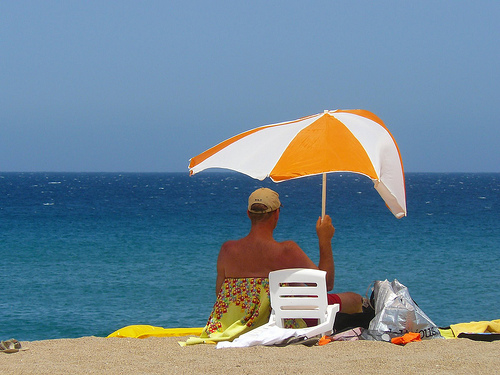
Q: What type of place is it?
A: It is an ocean.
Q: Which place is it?
A: It is an ocean.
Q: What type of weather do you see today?
A: It is clear.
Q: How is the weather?
A: It is clear.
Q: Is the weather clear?
A: Yes, it is clear.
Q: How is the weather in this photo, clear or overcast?
A: It is clear.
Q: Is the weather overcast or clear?
A: It is clear.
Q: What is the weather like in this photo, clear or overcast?
A: It is clear.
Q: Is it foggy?
A: No, it is clear.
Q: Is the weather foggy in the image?
A: No, it is clear.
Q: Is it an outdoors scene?
A: Yes, it is outdoors.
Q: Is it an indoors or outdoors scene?
A: It is outdoors.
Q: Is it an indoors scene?
A: No, it is outdoors.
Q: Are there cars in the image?
A: No, there are no cars.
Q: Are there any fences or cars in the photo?
A: No, there are no cars or fences.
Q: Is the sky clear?
A: Yes, the sky is clear.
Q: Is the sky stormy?
A: No, the sky is clear.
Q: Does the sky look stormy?
A: No, the sky is clear.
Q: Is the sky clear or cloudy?
A: The sky is clear.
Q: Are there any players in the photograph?
A: No, there are no players.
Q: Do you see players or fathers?
A: No, there are no players or fathers.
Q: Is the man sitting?
A: Yes, the man is sitting.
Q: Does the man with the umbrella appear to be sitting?
A: Yes, the man is sitting.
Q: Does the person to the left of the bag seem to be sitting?
A: Yes, the man is sitting.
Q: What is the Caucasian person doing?
A: The man is sitting.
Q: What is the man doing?
A: The man is sitting.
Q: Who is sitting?
A: The man is sitting.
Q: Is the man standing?
A: No, the man is sitting.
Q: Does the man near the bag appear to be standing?
A: No, the man is sitting.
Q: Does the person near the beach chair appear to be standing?
A: No, the man is sitting.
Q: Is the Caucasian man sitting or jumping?
A: The man is sitting.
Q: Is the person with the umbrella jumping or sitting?
A: The man is sitting.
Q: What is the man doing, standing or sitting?
A: The man is sitting.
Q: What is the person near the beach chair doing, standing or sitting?
A: The man is sitting.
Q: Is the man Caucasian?
A: Yes, the man is caucasian.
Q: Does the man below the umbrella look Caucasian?
A: Yes, the man is caucasian.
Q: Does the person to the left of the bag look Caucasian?
A: Yes, the man is caucasian.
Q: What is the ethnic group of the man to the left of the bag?
A: The man is caucasian.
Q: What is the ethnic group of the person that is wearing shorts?
A: The man is caucasian.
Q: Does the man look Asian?
A: No, the man is caucasian.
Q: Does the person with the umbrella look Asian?
A: No, the man is caucasian.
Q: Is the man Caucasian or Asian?
A: The man is caucasian.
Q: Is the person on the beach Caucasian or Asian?
A: The man is caucasian.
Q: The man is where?
A: The man is on the beach.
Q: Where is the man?
A: The man is on the beach.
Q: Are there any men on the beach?
A: Yes, there is a man on the beach.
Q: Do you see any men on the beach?
A: Yes, there is a man on the beach.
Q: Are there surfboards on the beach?
A: No, there is a man on the beach.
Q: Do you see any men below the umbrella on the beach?
A: Yes, there is a man below the umbrella.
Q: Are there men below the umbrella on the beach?
A: Yes, there is a man below the umbrella.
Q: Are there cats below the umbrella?
A: No, there is a man below the umbrella.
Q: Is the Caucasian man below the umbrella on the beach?
A: Yes, the man is below the umbrella.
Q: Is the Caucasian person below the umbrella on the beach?
A: Yes, the man is below the umbrella.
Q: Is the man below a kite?
A: No, the man is below the umbrella.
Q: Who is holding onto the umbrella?
A: The man is holding onto the umbrella.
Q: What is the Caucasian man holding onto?
A: The man is holding onto the umbrella.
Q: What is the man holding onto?
A: The man is holding onto the umbrella.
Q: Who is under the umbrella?
A: The man is under the umbrella.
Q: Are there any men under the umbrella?
A: Yes, there is a man under the umbrella.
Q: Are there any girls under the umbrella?
A: No, there is a man under the umbrella.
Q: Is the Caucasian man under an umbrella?
A: Yes, the man is under an umbrella.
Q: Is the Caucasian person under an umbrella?
A: Yes, the man is under an umbrella.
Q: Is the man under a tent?
A: No, the man is under an umbrella.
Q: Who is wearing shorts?
A: The man is wearing shorts.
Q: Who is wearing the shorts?
A: The man is wearing shorts.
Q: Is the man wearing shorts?
A: Yes, the man is wearing shorts.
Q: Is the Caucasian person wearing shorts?
A: Yes, the man is wearing shorts.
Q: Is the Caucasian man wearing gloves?
A: No, the man is wearing shorts.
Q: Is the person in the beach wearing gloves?
A: No, the man is wearing shorts.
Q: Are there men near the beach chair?
A: Yes, there is a man near the beach chair.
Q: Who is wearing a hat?
A: The man is wearing a hat.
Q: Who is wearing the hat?
A: The man is wearing a hat.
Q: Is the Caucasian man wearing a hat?
A: Yes, the man is wearing a hat.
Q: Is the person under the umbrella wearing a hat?
A: Yes, the man is wearing a hat.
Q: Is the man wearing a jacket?
A: No, the man is wearing a hat.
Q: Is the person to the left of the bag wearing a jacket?
A: No, the man is wearing a hat.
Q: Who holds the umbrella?
A: The man holds the umbrella.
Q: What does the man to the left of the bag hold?
A: The man holds the umbrella.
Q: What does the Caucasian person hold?
A: The man holds the umbrella.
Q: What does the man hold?
A: The man holds the umbrella.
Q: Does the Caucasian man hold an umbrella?
A: Yes, the man holds an umbrella.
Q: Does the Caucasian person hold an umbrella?
A: Yes, the man holds an umbrella.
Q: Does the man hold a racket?
A: No, the man holds an umbrella.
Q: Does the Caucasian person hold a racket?
A: No, the man holds an umbrella.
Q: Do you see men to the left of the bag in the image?
A: Yes, there is a man to the left of the bag.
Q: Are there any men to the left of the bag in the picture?
A: Yes, there is a man to the left of the bag.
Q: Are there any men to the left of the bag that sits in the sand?
A: Yes, there is a man to the left of the bag.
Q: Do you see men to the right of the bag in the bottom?
A: No, the man is to the left of the bag.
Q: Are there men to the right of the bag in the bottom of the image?
A: No, the man is to the left of the bag.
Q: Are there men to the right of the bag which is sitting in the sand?
A: No, the man is to the left of the bag.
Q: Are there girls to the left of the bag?
A: No, there is a man to the left of the bag.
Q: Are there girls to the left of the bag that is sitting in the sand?
A: No, there is a man to the left of the bag.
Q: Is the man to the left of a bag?
A: Yes, the man is to the left of a bag.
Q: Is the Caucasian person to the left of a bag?
A: Yes, the man is to the left of a bag.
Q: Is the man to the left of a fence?
A: No, the man is to the left of a bag.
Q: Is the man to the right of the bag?
A: No, the man is to the left of the bag.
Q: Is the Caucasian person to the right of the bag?
A: No, the man is to the left of the bag.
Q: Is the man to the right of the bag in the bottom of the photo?
A: No, the man is to the left of the bag.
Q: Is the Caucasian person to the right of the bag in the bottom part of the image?
A: No, the man is to the left of the bag.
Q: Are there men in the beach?
A: Yes, there is a man in the beach.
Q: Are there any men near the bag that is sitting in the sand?
A: Yes, there is a man near the bag.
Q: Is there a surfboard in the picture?
A: No, there are no surfboards.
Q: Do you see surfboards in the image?
A: No, there are no surfboards.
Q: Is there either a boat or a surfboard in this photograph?
A: No, there are no surfboards or boats.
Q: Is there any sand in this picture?
A: Yes, there is sand.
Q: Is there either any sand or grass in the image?
A: Yes, there is sand.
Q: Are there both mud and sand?
A: No, there is sand but no mud.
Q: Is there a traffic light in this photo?
A: No, there are no traffic lights.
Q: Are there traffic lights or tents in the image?
A: No, there are no traffic lights or tents.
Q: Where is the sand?
A: The sand is on the beach.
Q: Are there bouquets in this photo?
A: No, there are no bouquets.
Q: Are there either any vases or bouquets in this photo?
A: No, there are no bouquets or vases.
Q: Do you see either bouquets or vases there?
A: No, there are no bouquets or vases.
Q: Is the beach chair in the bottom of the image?
A: Yes, the beach chair is in the bottom of the image.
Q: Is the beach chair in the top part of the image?
A: No, the beach chair is in the bottom of the image.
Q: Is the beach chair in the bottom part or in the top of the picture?
A: The beach chair is in the bottom of the image.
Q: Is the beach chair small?
A: Yes, the beach chair is small.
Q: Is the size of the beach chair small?
A: Yes, the beach chair is small.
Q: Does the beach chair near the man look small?
A: Yes, the beach chair is small.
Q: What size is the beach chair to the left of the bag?
A: The beach chair is small.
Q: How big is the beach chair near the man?
A: The beach chair is small.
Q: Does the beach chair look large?
A: No, the beach chair is small.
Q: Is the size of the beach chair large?
A: No, the beach chair is small.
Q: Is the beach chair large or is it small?
A: The beach chair is small.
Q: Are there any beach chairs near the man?
A: Yes, there is a beach chair near the man.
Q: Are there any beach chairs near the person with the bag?
A: Yes, there is a beach chair near the man.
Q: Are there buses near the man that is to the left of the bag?
A: No, there is a beach chair near the man.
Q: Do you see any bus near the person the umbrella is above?
A: No, there is a beach chair near the man.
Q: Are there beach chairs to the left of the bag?
A: Yes, there is a beach chair to the left of the bag.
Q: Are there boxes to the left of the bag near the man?
A: No, there is a beach chair to the left of the bag.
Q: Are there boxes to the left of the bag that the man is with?
A: No, there is a beach chair to the left of the bag.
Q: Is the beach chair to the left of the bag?
A: Yes, the beach chair is to the left of the bag.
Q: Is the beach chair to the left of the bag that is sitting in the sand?
A: Yes, the beach chair is to the left of the bag.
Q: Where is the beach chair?
A: The beach chair is on the beach.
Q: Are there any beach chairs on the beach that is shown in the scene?
A: Yes, there is a beach chair on the beach.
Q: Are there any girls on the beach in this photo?
A: No, there is a beach chair on the beach.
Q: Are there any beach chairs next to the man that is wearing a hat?
A: Yes, there is a beach chair next to the man.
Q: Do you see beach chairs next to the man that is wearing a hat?
A: Yes, there is a beach chair next to the man.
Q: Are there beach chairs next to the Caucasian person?
A: Yes, there is a beach chair next to the man.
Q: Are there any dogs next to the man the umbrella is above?
A: No, there is a beach chair next to the man.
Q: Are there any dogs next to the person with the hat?
A: No, there is a beach chair next to the man.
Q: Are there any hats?
A: Yes, there is a hat.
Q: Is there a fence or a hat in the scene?
A: Yes, there is a hat.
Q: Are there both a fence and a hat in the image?
A: No, there is a hat but no fences.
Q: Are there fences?
A: No, there are no fences.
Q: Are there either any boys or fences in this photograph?
A: No, there are no fences or boys.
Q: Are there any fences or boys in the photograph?
A: No, there are no fences or boys.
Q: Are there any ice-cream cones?
A: No, there are no ice-cream cones.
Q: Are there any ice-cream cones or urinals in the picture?
A: No, there are no ice-cream cones or urinals.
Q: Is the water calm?
A: Yes, the water is calm.